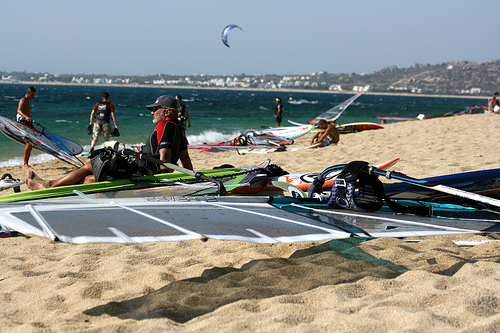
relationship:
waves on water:
[0, 129, 262, 166] [2, 81, 492, 165]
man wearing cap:
[25, 94, 195, 191] [146, 92, 182, 111]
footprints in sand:
[12, 256, 53, 280] [0, 237, 496, 333]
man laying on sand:
[25, 94, 195, 191] [1, 112, 499, 188]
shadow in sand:
[82, 238, 406, 320] [0, 237, 496, 333]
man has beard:
[25, 94, 195, 191] [152, 108, 167, 123]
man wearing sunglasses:
[25, 94, 195, 191] [151, 105, 159, 112]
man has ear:
[25, 94, 195, 191] [164, 106, 173, 117]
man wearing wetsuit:
[25, 94, 195, 191] [137, 120, 190, 175]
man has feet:
[25, 94, 195, 191] [24, 170, 51, 192]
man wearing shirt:
[82, 91, 121, 151] [91, 100, 114, 115]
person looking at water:
[273, 96, 285, 128] [2, 81, 492, 165]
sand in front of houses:
[3, 80, 497, 100] [1, 69, 378, 91]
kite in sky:
[218, 22, 243, 49] [2, 1, 496, 77]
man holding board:
[16, 86, 42, 166] [1, 117, 85, 170]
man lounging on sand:
[25, 94, 195, 191] [1, 112, 499, 188]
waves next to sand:
[3, 131, 234, 166] [1, 112, 499, 188]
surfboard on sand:
[4, 196, 496, 237] [0, 237, 496, 333]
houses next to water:
[1, 69, 378, 91] [2, 81, 492, 165]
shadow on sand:
[82, 238, 406, 320] [0, 237, 496, 333]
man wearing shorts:
[82, 91, 121, 151] [91, 121, 113, 141]